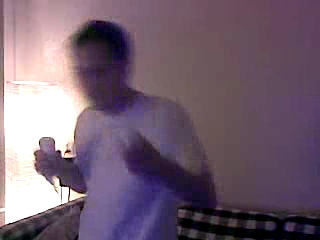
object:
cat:
[45, 203, 81, 240]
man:
[34, 19, 218, 239]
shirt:
[71, 94, 213, 239]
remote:
[37, 136, 54, 160]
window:
[4, 3, 64, 86]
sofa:
[1, 193, 318, 240]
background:
[0, 0, 320, 238]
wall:
[224, 5, 317, 206]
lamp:
[0, 81, 82, 223]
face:
[72, 50, 114, 107]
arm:
[122, 130, 216, 211]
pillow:
[169, 207, 320, 239]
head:
[62, 19, 135, 103]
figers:
[124, 138, 159, 174]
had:
[112, 128, 153, 174]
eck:
[106, 95, 129, 104]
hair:
[63, 19, 136, 67]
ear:
[117, 61, 130, 80]